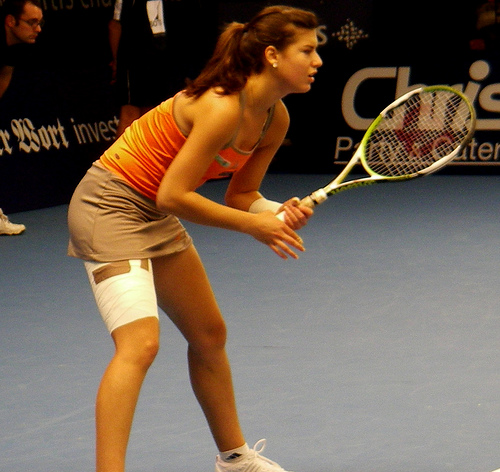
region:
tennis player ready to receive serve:
[65, 7, 477, 470]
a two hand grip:
[235, 172, 325, 272]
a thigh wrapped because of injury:
[68, 224, 158, 339]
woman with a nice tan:
[135, 4, 341, 259]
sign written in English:
[328, 57, 498, 187]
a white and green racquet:
[265, 82, 481, 232]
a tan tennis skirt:
[41, 162, 196, 270]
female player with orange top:
[95, 85, 278, 207]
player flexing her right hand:
[242, 186, 319, 267]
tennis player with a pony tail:
[162, 3, 329, 122]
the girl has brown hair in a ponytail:
[186, 2, 322, 128]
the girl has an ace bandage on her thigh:
[76, 233, 161, 340]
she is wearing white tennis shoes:
[213, 432, 284, 467]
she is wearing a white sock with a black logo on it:
[216, 441, 248, 462]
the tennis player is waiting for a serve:
[62, 8, 472, 463]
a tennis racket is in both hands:
[165, 10, 475, 253]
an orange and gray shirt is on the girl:
[100, 90, 278, 210]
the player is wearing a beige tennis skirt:
[65, 160, 191, 261]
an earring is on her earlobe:
[261, 42, 281, 68]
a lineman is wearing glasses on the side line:
[5, 2, 46, 238]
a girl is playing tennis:
[46, 5, 477, 464]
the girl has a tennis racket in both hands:
[261, 84, 478, 261]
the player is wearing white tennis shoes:
[212, 436, 279, 466]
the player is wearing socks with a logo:
[215, 440, 250, 465]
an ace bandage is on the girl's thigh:
[82, 245, 158, 334]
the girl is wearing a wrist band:
[246, 195, 281, 215]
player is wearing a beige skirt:
[60, 160, 192, 255]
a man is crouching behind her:
[0, 0, 45, 232]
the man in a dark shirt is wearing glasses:
[2, 0, 39, 50]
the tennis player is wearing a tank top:
[97, 80, 277, 210]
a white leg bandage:
[61, 225, 178, 351]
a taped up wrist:
[239, 175, 315, 237]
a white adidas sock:
[210, 433, 267, 468]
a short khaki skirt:
[54, 148, 220, 273]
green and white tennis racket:
[249, 80, 484, 245]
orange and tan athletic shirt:
[95, 67, 285, 215]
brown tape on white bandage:
[83, 259, 141, 295]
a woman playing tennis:
[32, 6, 453, 456]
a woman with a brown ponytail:
[177, 4, 348, 121]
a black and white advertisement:
[324, 47, 497, 221]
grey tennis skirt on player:
[60, 154, 202, 280]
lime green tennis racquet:
[291, 49, 457, 274]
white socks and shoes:
[195, 429, 310, 469]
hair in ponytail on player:
[207, 6, 342, 160]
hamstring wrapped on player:
[46, 217, 171, 338]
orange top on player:
[115, 76, 302, 246]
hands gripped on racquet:
[242, 182, 316, 274]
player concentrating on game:
[204, 2, 330, 117]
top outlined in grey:
[162, 67, 269, 193]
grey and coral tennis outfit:
[50, 82, 245, 301]